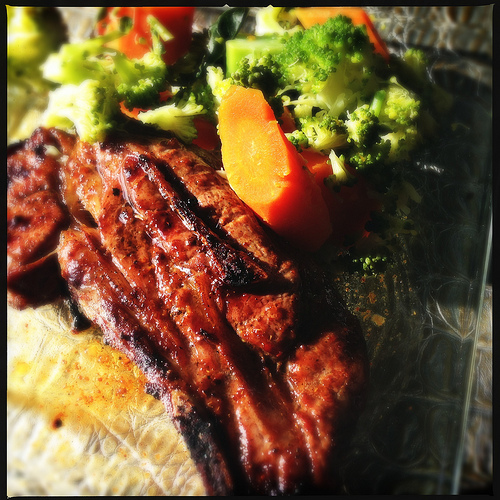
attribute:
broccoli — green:
[40, 21, 172, 105]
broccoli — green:
[234, 13, 429, 190]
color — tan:
[74, 172, 113, 218]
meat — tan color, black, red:
[5, 125, 373, 498]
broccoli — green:
[231, 14, 453, 191]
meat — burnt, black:
[17, 142, 361, 454]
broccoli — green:
[265, 11, 418, 177]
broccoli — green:
[287, 39, 419, 159]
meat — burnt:
[131, 155, 286, 305]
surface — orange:
[11, 320, 163, 480]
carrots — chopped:
[279, 11, 416, 87]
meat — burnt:
[83, 109, 374, 414]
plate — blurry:
[425, 13, 485, 45]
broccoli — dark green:
[237, 32, 441, 187]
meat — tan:
[39, 154, 247, 347]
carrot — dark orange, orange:
[214, 83, 336, 247]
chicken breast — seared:
[16, 130, 231, 326]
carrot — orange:
[219, 89, 328, 241]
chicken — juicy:
[116, 178, 197, 233]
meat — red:
[160, 213, 258, 411]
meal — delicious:
[9, 7, 429, 495]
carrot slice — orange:
[219, 78, 328, 245]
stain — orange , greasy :
[7, 323, 202, 496]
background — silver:
[358, 8, 495, 496]